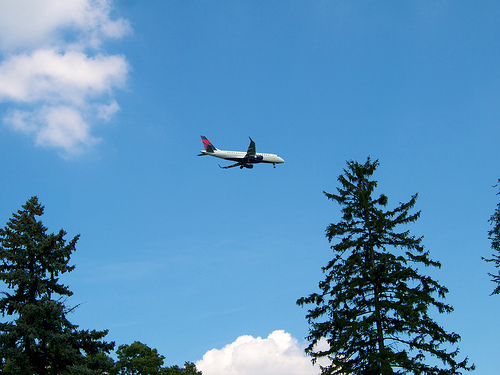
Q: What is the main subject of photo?
A: An airplane.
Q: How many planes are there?
A: 1.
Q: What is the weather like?
A: Warm with clear skies.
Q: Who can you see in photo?
A: No one.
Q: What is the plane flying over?
A: Pine trees.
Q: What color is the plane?
A: White.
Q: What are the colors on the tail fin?
A: Orange and blue.